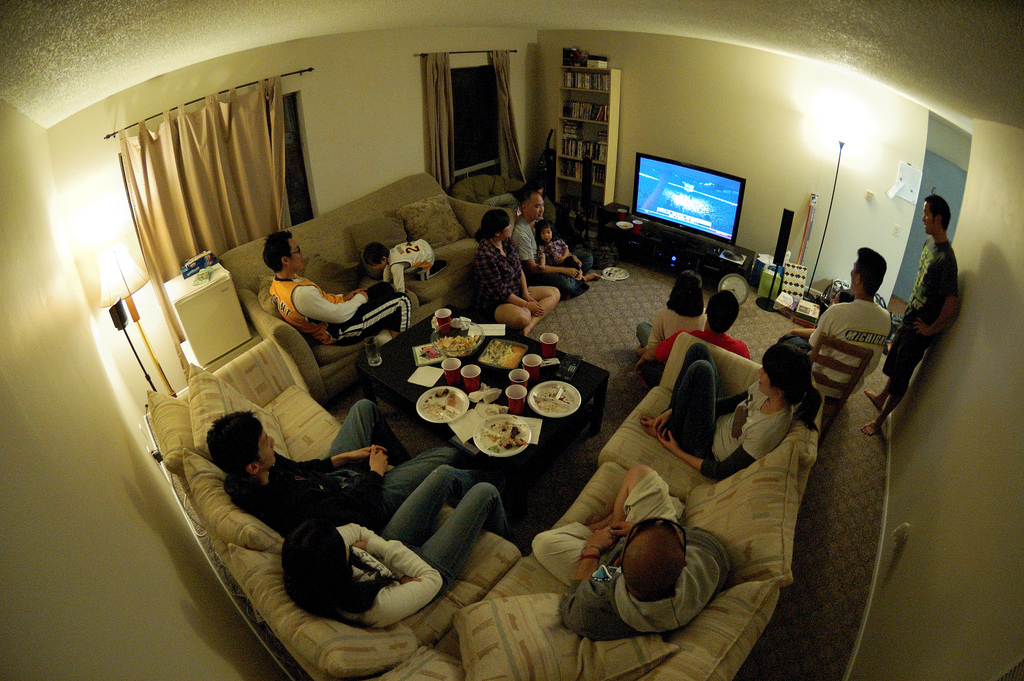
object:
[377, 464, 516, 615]
pants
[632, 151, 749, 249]
television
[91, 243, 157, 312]
light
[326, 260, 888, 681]
rug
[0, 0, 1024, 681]
room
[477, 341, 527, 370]
food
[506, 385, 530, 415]
drink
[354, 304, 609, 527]
table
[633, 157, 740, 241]
screen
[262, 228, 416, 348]
male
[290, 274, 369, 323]
jersey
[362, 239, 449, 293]
child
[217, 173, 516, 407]
couch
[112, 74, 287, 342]
curtain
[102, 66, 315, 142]
rod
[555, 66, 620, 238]
shelf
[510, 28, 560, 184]
corner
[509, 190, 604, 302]
man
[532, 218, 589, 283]
girl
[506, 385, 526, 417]
cups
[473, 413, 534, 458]
plates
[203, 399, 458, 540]
male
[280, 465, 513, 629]
female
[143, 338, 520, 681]
couch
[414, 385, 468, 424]
plate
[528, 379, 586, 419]
plate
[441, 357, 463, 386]
vessel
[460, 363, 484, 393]
vessel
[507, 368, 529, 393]
vessel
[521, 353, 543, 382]
vessel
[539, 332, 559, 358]
vessel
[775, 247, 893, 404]
person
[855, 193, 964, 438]
person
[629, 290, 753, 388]
person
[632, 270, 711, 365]
person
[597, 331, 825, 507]
sofa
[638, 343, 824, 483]
person